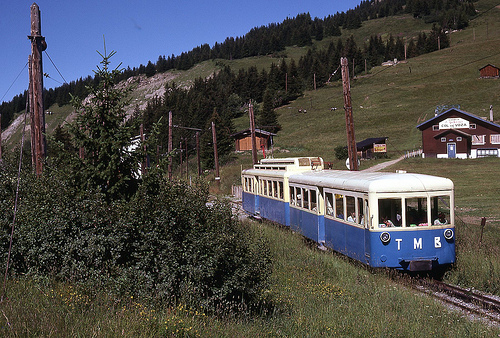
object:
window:
[286, 186, 295, 208]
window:
[295, 187, 301, 207]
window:
[323, 192, 335, 217]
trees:
[75, 32, 135, 299]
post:
[209, 122, 222, 193]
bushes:
[0, 40, 287, 321]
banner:
[437, 117, 470, 129]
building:
[417, 104, 500, 159]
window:
[377, 197, 404, 233]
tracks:
[199, 192, 246, 216]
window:
[344, 195, 358, 226]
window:
[309, 190, 317, 214]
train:
[241, 155, 457, 271]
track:
[415, 276, 498, 321]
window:
[333, 192, 345, 221]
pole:
[247, 102, 258, 165]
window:
[405, 195, 427, 226]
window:
[430, 195, 450, 224]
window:
[377, 198, 402, 226]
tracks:
[403, 275, 498, 323]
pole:
[341, 56, 360, 170]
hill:
[0, 32, 496, 205]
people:
[382, 218, 396, 228]